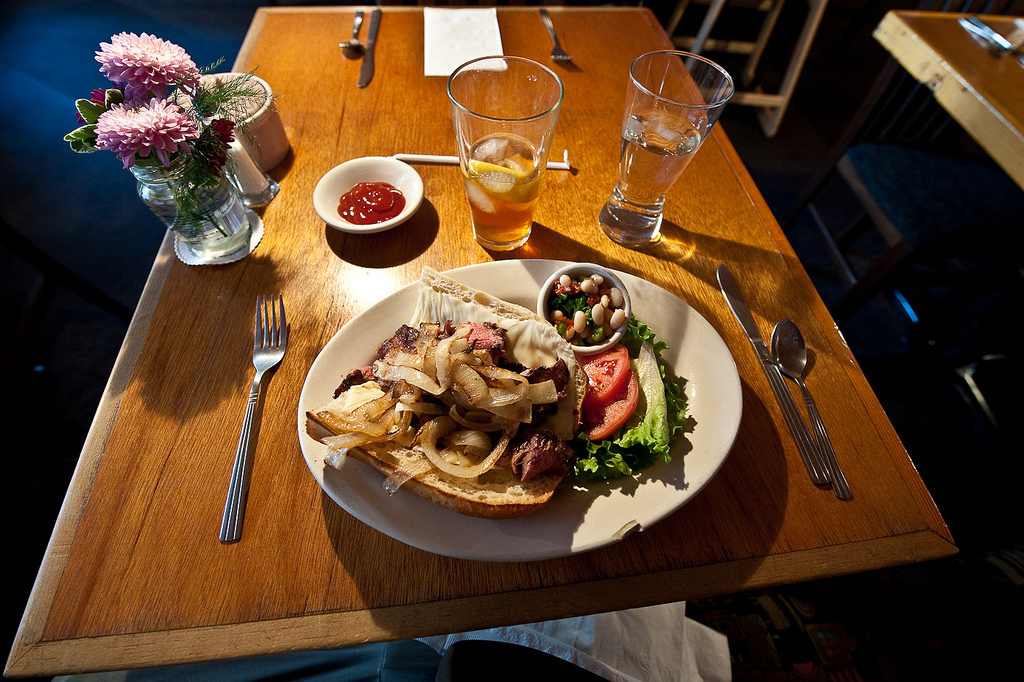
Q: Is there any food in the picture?
A: Yes, there is food.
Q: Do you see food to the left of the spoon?
A: Yes, there is food to the left of the spoon.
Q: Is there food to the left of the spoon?
A: Yes, there is food to the left of the spoon.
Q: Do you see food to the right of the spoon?
A: No, the food is to the left of the spoon.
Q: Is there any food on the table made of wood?
A: Yes, there is food on the table.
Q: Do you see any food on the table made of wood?
A: Yes, there is food on the table.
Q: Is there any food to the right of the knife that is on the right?
A: No, the food is to the left of the knife.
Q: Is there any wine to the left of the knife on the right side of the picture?
A: No, there is food to the left of the knife.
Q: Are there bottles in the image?
A: No, there are no bottles.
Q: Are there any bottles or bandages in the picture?
A: No, there are no bottles or bandages.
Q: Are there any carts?
A: No, there are no carts.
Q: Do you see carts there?
A: No, there are no carts.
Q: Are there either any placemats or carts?
A: No, there are no carts or placemats.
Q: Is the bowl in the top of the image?
A: Yes, the bowl is in the top of the image.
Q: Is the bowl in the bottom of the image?
A: No, the bowl is in the top of the image.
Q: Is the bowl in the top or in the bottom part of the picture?
A: The bowl is in the top of the image.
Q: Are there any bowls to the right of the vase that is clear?
A: Yes, there is a bowl to the right of the vase.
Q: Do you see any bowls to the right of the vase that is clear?
A: Yes, there is a bowl to the right of the vase.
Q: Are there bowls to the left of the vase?
A: No, the bowl is to the right of the vase.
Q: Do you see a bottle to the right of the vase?
A: No, there is a bowl to the right of the vase.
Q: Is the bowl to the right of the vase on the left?
A: Yes, the bowl is to the right of the vase.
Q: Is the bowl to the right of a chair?
A: No, the bowl is to the right of the vase.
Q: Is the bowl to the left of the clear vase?
A: No, the bowl is to the right of the vase.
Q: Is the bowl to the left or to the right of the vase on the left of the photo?
A: The bowl is to the right of the vase.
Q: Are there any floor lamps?
A: No, there are no floor lamps.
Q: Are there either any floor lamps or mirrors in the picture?
A: No, there are no floor lamps or mirrors.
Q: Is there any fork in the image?
A: Yes, there is a fork.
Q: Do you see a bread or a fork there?
A: Yes, there is a fork.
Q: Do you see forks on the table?
A: Yes, there is a fork on the table.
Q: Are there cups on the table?
A: No, there is a fork on the table.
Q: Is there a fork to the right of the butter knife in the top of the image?
A: Yes, there is a fork to the right of the butter knife.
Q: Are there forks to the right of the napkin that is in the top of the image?
A: Yes, there is a fork to the right of the napkin.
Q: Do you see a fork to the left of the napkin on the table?
A: No, the fork is to the right of the napkin.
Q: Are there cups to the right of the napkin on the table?
A: No, there is a fork to the right of the napkin.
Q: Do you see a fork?
A: Yes, there is a fork.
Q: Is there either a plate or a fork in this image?
A: Yes, there is a fork.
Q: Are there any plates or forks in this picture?
A: Yes, there is a fork.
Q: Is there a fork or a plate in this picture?
A: Yes, there is a fork.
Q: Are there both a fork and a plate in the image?
A: Yes, there are both a fork and a plate.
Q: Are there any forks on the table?
A: Yes, there is a fork on the table.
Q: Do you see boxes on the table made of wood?
A: No, there is a fork on the table.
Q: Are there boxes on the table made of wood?
A: No, there is a fork on the table.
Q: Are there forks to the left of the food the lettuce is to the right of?
A: Yes, there is a fork to the left of the food.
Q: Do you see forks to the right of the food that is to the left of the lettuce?
A: No, the fork is to the left of the food.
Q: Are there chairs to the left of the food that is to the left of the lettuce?
A: No, there is a fork to the left of the food.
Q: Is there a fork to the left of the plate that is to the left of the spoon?
A: Yes, there is a fork to the left of the plate.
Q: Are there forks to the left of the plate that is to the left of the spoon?
A: Yes, there is a fork to the left of the plate.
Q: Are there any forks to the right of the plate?
A: No, the fork is to the left of the plate.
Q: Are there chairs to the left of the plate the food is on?
A: No, there is a fork to the left of the plate.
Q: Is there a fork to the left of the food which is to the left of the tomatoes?
A: Yes, there is a fork to the left of the food.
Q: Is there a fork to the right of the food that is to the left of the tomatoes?
A: No, the fork is to the left of the food.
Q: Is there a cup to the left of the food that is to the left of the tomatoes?
A: No, there is a fork to the left of the food.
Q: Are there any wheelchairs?
A: No, there are no wheelchairs.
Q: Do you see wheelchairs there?
A: No, there are no wheelchairs.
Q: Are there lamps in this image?
A: No, there are no lamps.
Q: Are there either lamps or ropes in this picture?
A: No, there are no lamps or ropes.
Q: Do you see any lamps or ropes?
A: No, there are no lamps or ropes.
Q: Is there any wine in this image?
A: No, there is no wine.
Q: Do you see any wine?
A: No, there is no wine.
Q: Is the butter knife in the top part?
A: Yes, the butter knife is in the top of the image.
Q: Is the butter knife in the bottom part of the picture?
A: No, the butter knife is in the top of the image.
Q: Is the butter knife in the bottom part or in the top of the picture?
A: The butter knife is in the top of the image.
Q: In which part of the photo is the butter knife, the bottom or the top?
A: The butter knife is in the top of the image.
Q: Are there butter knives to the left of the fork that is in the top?
A: Yes, there is a butter knife to the left of the fork.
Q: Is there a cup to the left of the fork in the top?
A: No, there is a butter knife to the left of the fork.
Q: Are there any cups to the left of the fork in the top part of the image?
A: No, there is a butter knife to the left of the fork.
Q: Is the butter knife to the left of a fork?
A: Yes, the butter knife is to the left of a fork.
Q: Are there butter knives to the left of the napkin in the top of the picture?
A: Yes, there is a butter knife to the left of the napkin.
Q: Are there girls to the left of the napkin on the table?
A: No, there is a butter knife to the left of the napkin.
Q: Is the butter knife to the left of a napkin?
A: Yes, the butter knife is to the left of a napkin.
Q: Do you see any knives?
A: Yes, there is a knife.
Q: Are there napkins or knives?
A: Yes, there is a knife.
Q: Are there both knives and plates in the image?
A: Yes, there are both a knife and a plate.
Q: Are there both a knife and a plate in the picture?
A: Yes, there are both a knife and a plate.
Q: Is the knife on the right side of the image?
A: Yes, the knife is on the right of the image.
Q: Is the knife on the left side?
A: No, the knife is on the right of the image.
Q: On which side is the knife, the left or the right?
A: The knife is on the right of the image.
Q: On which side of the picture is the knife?
A: The knife is on the right of the image.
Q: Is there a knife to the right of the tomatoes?
A: Yes, there is a knife to the right of the tomatoes.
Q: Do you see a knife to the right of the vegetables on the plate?
A: Yes, there is a knife to the right of the tomatoes.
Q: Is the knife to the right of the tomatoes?
A: Yes, the knife is to the right of the tomatoes.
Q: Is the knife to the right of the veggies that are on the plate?
A: Yes, the knife is to the right of the tomatoes.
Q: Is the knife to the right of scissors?
A: No, the knife is to the right of the tomatoes.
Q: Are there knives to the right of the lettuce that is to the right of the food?
A: Yes, there is a knife to the right of the lettuce.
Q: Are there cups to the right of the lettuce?
A: No, there is a knife to the right of the lettuce.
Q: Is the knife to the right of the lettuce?
A: Yes, the knife is to the right of the lettuce.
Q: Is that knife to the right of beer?
A: No, the knife is to the right of the lettuce.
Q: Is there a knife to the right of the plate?
A: Yes, there is a knife to the right of the plate.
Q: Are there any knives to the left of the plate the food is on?
A: No, the knife is to the right of the plate.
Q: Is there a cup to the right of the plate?
A: No, there is a knife to the right of the plate.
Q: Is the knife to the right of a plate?
A: Yes, the knife is to the right of a plate.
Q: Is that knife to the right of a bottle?
A: No, the knife is to the right of a plate.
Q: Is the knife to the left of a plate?
A: No, the knife is to the right of a plate.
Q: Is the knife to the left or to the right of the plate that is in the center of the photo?
A: The knife is to the right of the plate.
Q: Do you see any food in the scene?
A: Yes, there is food.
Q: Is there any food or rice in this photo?
A: Yes, there is food.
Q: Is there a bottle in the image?
A: No, there are no bottles.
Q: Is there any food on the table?
A: Yes, there is food on the table.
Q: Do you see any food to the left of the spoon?
A: Yes, there is food to the left of the spoon.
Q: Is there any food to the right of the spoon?
A: No, the food is to the left of the spoon.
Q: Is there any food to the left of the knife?
A: Yes, there is food to the left of the knife.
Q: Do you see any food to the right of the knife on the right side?
A: No, the food is to the left of the knife.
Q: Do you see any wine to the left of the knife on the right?
A: No, there is food to the left of the knife.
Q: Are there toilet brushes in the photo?
A: No, there are no toilet brushes.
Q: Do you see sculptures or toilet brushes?
A: No, there are no toilet brushes or sculptures.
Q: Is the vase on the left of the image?
A: Yes, the vase is on the left of the image.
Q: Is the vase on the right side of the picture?
A: No, the vase is on the left of the image.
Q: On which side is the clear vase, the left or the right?
A: The vase is on the left of the image.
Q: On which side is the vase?
A: The vase is on the left of the image.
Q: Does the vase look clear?
A: Yes, the vase is clear.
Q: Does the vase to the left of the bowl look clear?
A: Yes, the vase is clear.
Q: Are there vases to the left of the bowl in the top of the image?
A: Yes, there is a vase to the left of the bowl.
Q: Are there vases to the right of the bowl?
A: No, the vase is to the left of the bowl.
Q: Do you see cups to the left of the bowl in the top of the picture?
A: No, there is a vase to the left of the bowl.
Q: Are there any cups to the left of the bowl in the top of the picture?
A: No, there is a vase to the left of the bowl.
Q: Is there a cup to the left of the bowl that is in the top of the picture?
A: No, there is a vase to the left of the bowl.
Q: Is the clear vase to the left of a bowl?
A: Yes, the vase is to the left of a bowl.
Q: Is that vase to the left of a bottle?
A: No, the vase is to the left of a bowl.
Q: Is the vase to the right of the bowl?
A: No, the vase is to the left of the bowl.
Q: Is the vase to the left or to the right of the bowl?
A: The vase is to the left of the bowl.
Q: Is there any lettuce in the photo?
A: Yes, there is lettuce.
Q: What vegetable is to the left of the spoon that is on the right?
A: The vegetable is lettuce.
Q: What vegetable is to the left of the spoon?
A: The vegetable is lettuce.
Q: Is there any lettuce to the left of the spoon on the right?
A: Yes, there is lettuce to the left of the spoon.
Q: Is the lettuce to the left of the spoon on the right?
A: Yes, the lettuce is to the left of the spoon.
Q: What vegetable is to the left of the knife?
A: The vegetable is lettuce.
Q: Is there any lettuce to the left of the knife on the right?
A: Yes, there is lettuce to the left of the knife.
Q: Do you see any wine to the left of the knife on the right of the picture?
A: No, there is lettuce to the left of the knife.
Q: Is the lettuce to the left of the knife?
A: Yes, the lettuce is to the left of the knife.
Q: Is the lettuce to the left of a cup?
A: No, the lettuce is to the left of the knife.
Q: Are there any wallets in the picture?
A: No, there are no wallets.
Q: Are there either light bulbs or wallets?
A: No, there are no wallets or light bulbs.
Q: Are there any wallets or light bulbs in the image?
A: No, there are no wallets or light bulbs.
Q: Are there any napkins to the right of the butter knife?
A: Yes, there is a napkin to the right of the butter knife.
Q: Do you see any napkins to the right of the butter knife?
A: Yes, there is a napkin to the right of the butter knife.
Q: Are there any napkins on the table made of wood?
A: Yes, there is a napkin on the table.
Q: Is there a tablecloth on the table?
A: No, there is a napkin on the table.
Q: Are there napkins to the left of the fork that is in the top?
A: Yes, there is a napkin to the left of the fork.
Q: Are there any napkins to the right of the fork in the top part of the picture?
A: No, the napkin is to the left of the fork.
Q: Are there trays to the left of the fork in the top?
A: No, there is a napkin to the left of the fork.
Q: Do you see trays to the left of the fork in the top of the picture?
A: No, there is a napkin to the left of the fork.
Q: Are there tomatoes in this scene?
A: Yes, there are tomatoes.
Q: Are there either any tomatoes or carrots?
A: Yes, there are tomatoes.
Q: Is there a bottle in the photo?
A: No, there are no bottles.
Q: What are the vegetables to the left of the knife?
A: The vegetables are tomatoes.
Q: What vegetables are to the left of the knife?
A: The vegetables are tomatoes.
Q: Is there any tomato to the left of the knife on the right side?
A: Yes, there are tomatoes to the left of the knife.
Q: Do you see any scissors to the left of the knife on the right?
A: No, there are tomatoes to the left of the knife.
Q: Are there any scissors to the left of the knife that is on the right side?
A: No, there are tomatoes to the left of the knife.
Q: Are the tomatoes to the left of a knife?
A: Yes, the tomatoes are to the left of a knife.